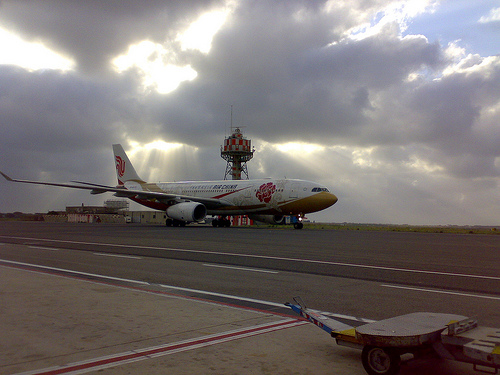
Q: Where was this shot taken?
A: Air strip.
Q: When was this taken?
A: Daytime.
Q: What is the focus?
A: Airplane taking off.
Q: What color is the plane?
A: White and gold.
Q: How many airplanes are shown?
A: 1.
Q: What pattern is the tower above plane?
A: Checkered.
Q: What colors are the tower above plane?
A: Red and white.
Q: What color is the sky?
A: Blue.